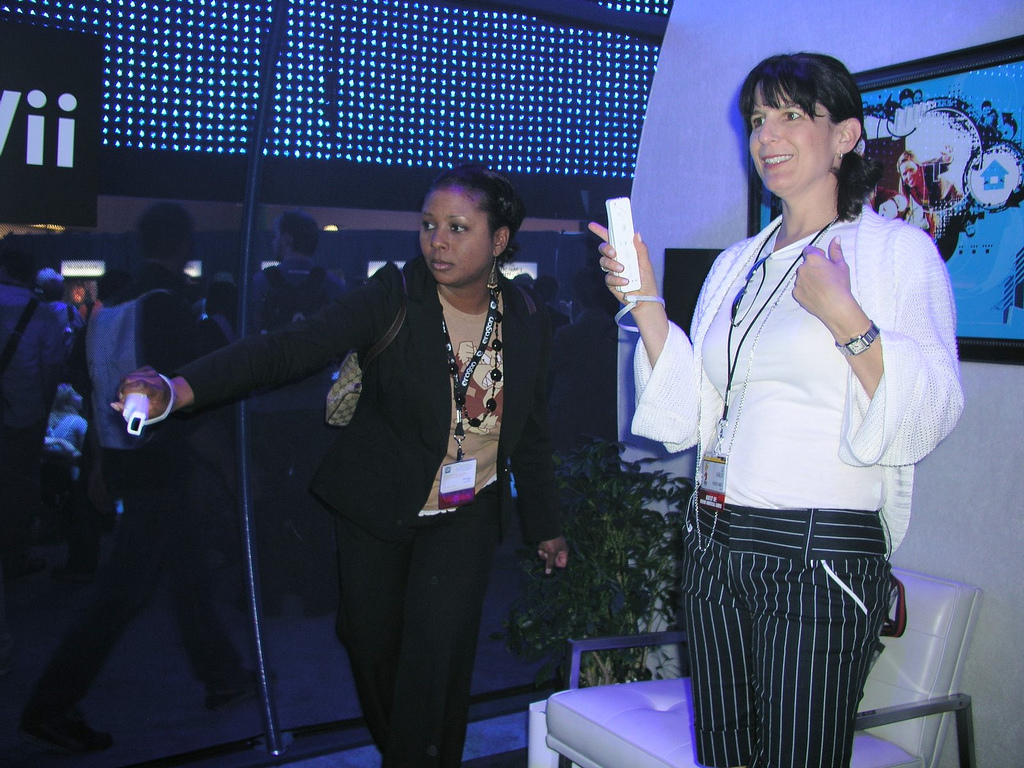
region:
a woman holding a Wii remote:
[590, 54, 875, 331]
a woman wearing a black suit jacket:
[146, 171, 581, 535]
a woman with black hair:
[737, 50, 886, 222]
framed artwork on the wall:
[743, 37, 1016, 345]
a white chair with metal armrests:
[548, 576, 997, 766]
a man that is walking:
[40, 202, 287, 721]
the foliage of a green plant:
[512, 437, 712, 695]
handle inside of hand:
[597, 196, 643, 289]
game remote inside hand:
[104, 386, 159, 437]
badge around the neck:
[433, 463, 485, 506]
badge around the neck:
[687, 452, 741, 500]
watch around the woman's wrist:
[834, 317, 885, 359]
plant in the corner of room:
[515, 449, 702, 688]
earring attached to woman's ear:
[483, 253, 510, 295]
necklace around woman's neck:
[436, 288, 506, 424]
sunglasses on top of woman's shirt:
[715, 244, 774, 327]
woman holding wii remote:
[582, 48, 968, 763]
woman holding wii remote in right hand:
[94, 163, 582, 764]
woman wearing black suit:
[105, 159, 577, 754]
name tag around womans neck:
[685, 49, 901, 522]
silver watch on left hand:
[788, 238, 894, 404]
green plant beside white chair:
[511, 438, 984, 765]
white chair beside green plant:
[497, 443, 975, 764]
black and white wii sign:
[1, 23, 103, 221]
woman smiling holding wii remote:
[612, 46, 904, 759]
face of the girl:
[362, 133, 552, 342]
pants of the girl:
[678, 528, 923, 740]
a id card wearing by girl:
[416, 313, 544, 547]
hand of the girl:
[768, 255, 936, 348]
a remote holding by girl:
[599, 162, 683, 353]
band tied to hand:
[84, 356, 231, 492]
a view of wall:
[114, 25, 631, 225]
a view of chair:
[480, 623, 692, 760]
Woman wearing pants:
[315, 460, 518, 765]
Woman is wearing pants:
[304, 473, 516, 765]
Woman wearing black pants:
[314, 462, 515, 766]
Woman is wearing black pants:
[317, 472, 521, 766]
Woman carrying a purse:
[320, 250, 419, 429]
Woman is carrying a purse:
[314, 251, 428, 430]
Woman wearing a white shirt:
[623, 200, 969, 555]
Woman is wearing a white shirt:
[607, 203, 985, 543]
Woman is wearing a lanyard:
[687, 196, 858, 516]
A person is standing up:
[41, 191, 264, 727]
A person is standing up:
[261, 194, 335, 606]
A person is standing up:
[530, 264, 581, 329]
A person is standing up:
[19, 266, 90, 336]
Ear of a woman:
[830, 114, 869, 163]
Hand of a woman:
[792, 228, 860, 340]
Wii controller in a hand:
[599, 190, 651, 307]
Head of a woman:
[410, 162, 525, 292]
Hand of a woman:
[534, 521, 574, 579]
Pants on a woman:
[673, 493, 901, 766]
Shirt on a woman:
[710, 217, 878, 519]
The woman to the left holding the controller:
[94, 215, 597, 725]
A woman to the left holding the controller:
[96, 193, 631, 740]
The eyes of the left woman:
[412, 212, 480, 241]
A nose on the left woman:
[426, 229, 455, 246]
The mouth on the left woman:
[415, 250, 467, 274]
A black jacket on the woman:
[203, 265, 592, 540]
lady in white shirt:
[608, 191, 957, 523]